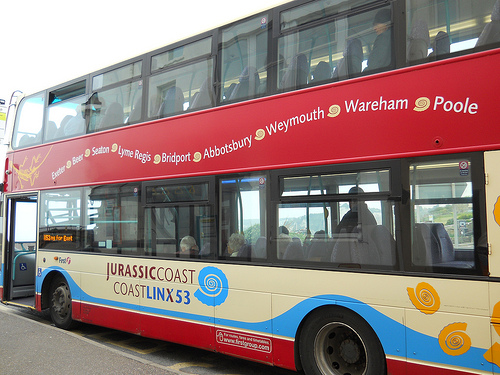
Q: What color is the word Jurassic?
A: Brown.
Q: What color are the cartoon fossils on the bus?
A: Blue and yellow.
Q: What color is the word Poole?
A: White.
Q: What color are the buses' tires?
A: Black.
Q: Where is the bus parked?
A: A parking lot.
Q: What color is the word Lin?
A: Blue.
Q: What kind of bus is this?
A: A double decker.